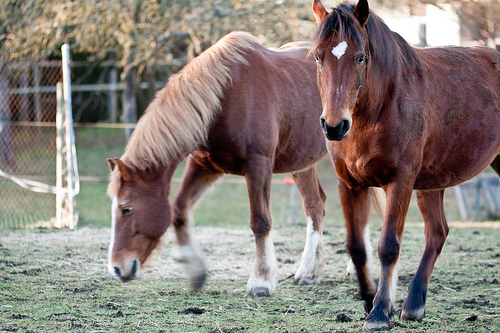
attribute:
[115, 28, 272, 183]
mane — long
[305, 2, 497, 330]
horse — brown, large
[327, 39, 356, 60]
spot — white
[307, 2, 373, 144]
face — horse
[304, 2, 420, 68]
mane — brown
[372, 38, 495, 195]
fur — horse, brown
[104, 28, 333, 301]
horse — large, brown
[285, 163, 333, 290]
leg — white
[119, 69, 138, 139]
trunk — tree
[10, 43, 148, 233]
fence — silver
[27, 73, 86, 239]
pole — metal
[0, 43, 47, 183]
trunk — brown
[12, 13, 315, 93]
branches — brown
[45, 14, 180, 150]
tree — large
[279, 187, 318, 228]
pole — metal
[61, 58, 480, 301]
horses — brown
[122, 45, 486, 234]
horses — brown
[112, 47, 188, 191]
mane — blonde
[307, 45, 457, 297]
horse — brown, black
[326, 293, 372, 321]
hoof — black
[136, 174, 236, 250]
leg — brown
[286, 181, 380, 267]
leg — brown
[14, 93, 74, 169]
fence — metal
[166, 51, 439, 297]
horses — brown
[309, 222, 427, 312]
patches — black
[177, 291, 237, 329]
grass — green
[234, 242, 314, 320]
feet — furry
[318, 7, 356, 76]
patch — white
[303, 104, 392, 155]
nose — black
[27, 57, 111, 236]
fence — metal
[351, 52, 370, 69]
eyes —  dark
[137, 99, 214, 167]
mane — blonde